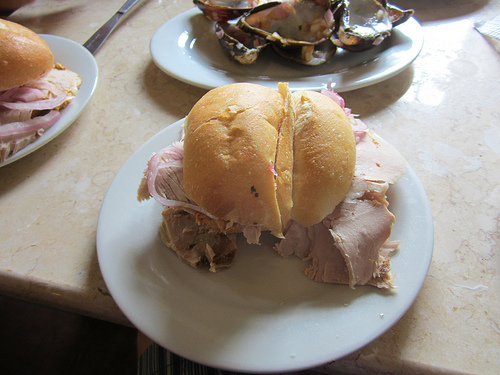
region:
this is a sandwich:
[138, 80, 402, 316]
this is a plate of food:
[185, 5, 417, 87]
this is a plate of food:
[2, 23, 100, 176]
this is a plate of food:
[0, 32, 101, 176]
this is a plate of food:
[105, 70, 430, 363]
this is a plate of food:
[145, 3, 422, 102]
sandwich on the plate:
[147, 71, 413, 231]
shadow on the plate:
[116, 258, 182, 315]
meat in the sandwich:
[151, 152, 197, 231]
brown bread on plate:
[211, 90, 326, 181]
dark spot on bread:
[223, 171, 278, 225]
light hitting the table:
[398, 70, 464, 131]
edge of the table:
[2, 248, 102, 332]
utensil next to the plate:
[75, 2, 146, 42]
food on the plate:
[181, 3, 422, 72]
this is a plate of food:
[99, 77, 436, 370]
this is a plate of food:
[2, 26, 105, 173]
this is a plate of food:
[145, 2, 422, 86]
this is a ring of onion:
[145, 149, 215, 239]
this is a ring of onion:
[317, 82, 377, 159]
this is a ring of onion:
[0, 85, 77, 112]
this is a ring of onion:
[5, 117, 62, 134]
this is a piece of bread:
[5, 23, 59, 79]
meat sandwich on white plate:
[94, 69, 440, 374]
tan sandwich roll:
[171, 77, 358, 247]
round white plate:
[90, 80, 441, 373]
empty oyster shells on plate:
[146, 0, 430, 97]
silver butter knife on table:
[78, 0, 155, 56]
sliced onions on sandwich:
[0, 81, 82, 140]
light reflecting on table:
[413, 11, 477, 107]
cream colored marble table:
[3, 2, 498, 372]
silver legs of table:
[124, 323, 212, 374]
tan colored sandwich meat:
[296, 118, 409, 310]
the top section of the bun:
[182, 80, 357, 236]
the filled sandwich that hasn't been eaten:
[137, 73, 407, 295]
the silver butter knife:
[79, 2, 148, 55]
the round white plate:
[97, 113, 432, 373]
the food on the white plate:
[95, 84, 432, 373]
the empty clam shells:
[192, 0, 412, 65]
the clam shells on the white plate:
[150, 0, 424, 94]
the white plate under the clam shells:
[151, 1, 423, 89]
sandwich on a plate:
[98, 83, 441, 374]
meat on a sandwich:
[136, 88, 394, 294]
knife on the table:
[78, 1, 152, 53]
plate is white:
[97, 116, 433, 373]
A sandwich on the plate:
[85, 70, 450, 370]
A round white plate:
[141, 0, 433, 102]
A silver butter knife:
[78, 0, 155, 63]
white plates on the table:
[5, 0, 432, 362]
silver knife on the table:
[97, 0, 143, 52]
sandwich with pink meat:
[148, 81, 398, 284]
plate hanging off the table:
[88, 105, 426, 365]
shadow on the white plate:
[132, 219, 324, 344]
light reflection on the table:
[393, 15, 468, 109]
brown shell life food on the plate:
[188, 2, 406, 69]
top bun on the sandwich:
[181, 76, 348, 215]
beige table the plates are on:
[6, 3, 491, 368]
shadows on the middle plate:
[180, 14, 414, 84]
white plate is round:
[95, 106, 435, 371]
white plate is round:
[0, 32, 100, 165]